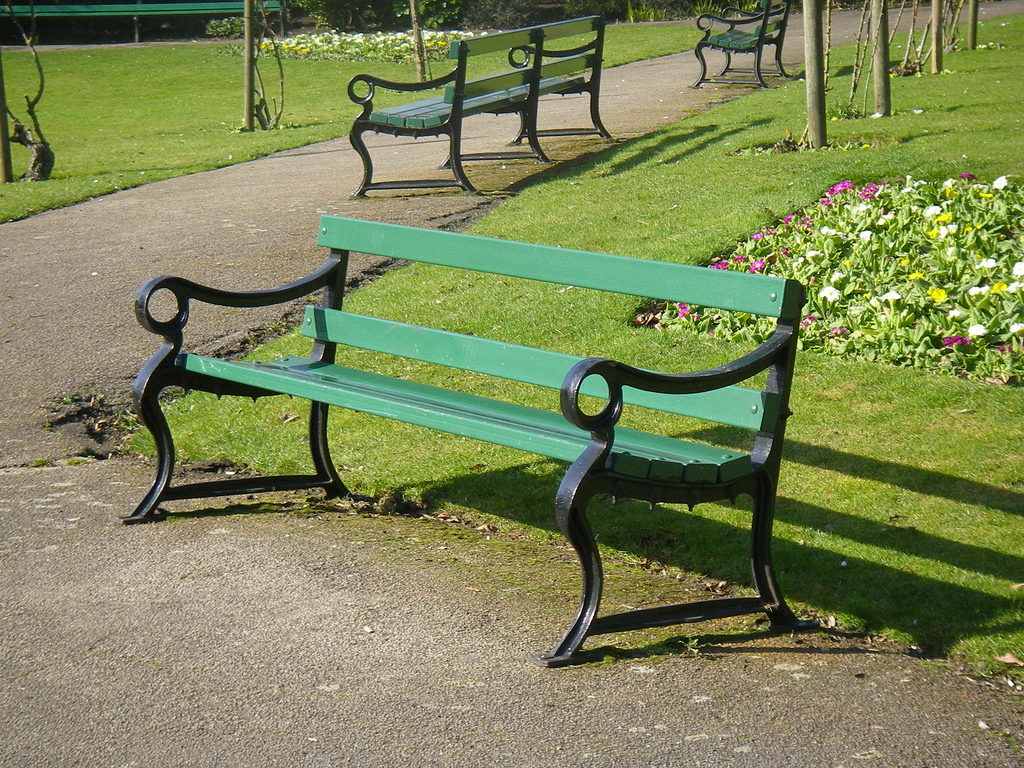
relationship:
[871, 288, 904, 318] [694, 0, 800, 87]
flower behind bench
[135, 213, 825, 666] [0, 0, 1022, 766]
bench on sidewalk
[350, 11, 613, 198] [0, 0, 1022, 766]
bench on sidewalk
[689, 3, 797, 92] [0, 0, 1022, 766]
bench on sidewalk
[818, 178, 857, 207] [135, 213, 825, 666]
flower behind bench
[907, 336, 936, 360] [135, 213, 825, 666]
flower behind bench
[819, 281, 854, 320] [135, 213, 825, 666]
flower behind bench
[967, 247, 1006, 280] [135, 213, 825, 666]
flower behind bench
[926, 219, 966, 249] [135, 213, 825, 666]
flower behind bench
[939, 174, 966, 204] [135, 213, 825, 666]
flower behind bench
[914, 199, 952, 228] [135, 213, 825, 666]
flower behind bench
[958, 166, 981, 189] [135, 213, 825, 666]
flower behind bench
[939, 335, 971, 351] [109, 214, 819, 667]
flowers behind bench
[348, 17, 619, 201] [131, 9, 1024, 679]
bench near grass